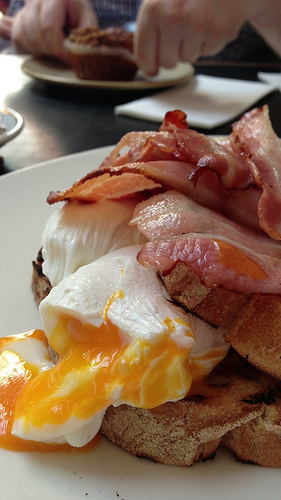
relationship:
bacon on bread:
[47, 105, 280, 288] [156, 254, 279, 378]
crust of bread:
[103, 405, 255, 467] [33, 250, 279, 467]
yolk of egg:
[1, 335, 186, 452] [3, 202, 227, 455]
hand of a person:
[10, 2, 96, 60] [6, 1, 279, 76]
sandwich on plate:
[1, 106, 279, 472] [1, 134, 278, 498]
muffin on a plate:
[64, 21, 139, 80] [21, 52, 197, 91]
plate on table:
[1, 134, 278, 498] [2, 53, 279, 171]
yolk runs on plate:
[1, 335, 186, 452] [1, 134, 278, 498]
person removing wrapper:
[6, 1, 279, 76] [62, 41, 140, 80]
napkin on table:
[115, 72, 278, 128] [2, 53, 279, 171]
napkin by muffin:
[115, 72, 278, 128] [64, 21, 139, 80]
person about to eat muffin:
[6, 1, 279, 76] [64, 21, 139, 80]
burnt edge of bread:
[33, 250, 44, 303] [33, 250, 279, 467]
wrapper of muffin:
[62, 41, 140, 80] [64, 21, 139, 80]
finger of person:
[134, 20, 158, 78] [6, 1, 279, 76]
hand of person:
[10, 2, 96, 60] [6, 1, 279, 76]